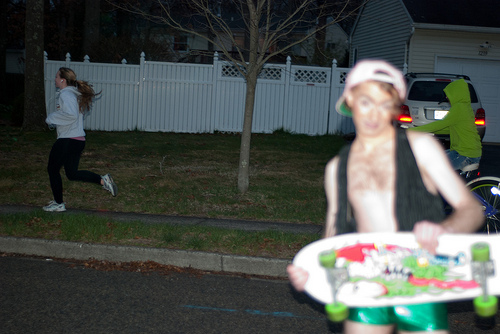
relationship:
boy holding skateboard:
[280, 45, 492, 334] [278, 219, 499, 318]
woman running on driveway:
[29, 57, 127, 218] [76, 195, 315, 239]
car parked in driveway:
[405, 65, 492, 140] [441, 133, 495, 171]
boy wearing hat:
[280, 45, 492, 334] [328, 55, 413, 116]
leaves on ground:
[77, 256, 215, 276] [3, 263, 294, 329]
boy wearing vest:
[280, 45, 492, 334] [327, 127, 448, 237]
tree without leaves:
[121, 4, 319, 197] [124, 1, 365, 65]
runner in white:
[29, 57, 127, 218] [39, 85, 89, 139]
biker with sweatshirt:
[421, 76, 499, 136] [405, 65, 492, 140]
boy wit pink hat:
[280, 45, 492, 334] [328, 55, 413, 116]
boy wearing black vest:
[280, 45, 492, 334] [327, 127, 448, 237]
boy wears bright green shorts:
[280, 45, 492, 334] [344, 299, 450, 334]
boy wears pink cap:
[280, 45, 492, 334] [328, 55, 413, 116]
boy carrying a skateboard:
[280, 45, 492, 334] [278, 219, 499, 318]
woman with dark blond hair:
[29, 57, 127, 218] [49, 64, 106, 117]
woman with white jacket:
[29, 57, 127, 218] [39, 85, 89, 139]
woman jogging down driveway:
[29, 57, 127, 218] [76, 195, 315, 239]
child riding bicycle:
[405, 65, 492, 140] [462, 159, 499, 233]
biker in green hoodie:
[421, 76, 499, 136] [405, 65, 492, 140]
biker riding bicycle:
[421, 76, 499, 136] [462, 159, 499, 233]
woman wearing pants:
[29, 57, 127, 218] [44, 135, 104, 201]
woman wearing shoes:
[29, 57, 127, 218] [119, 174, 413, 216]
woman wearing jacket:
[29, 57, 127, 218] [39, 85, 89, 139]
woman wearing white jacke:
[29, 57, 127, 218] [39, 85, 89, 139]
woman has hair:
[29, 57, 127, 218] [49, 64, 106, 117]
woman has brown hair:
[29, 57, 127, 218] [49, 64, 106, 117]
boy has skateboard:
[280, 45, 492, 334] [278, 219, 499, 318]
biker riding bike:
[421, 76, 499, 136] [462, 159, 499, 233]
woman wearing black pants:
[29, 57, 127, 218] [44, 135, 104, 201]